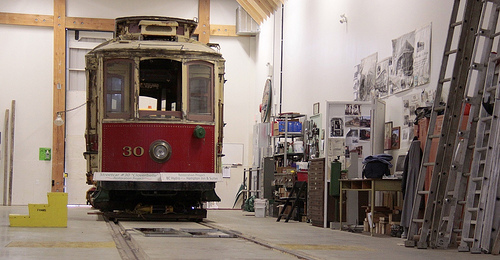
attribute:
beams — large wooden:
[51, 2, 67, 192]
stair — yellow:
[45, 187, 70, 209]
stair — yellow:
[27, 200, 50, 217]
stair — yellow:
[9, 210, 31, 227]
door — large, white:
[79, 69, 117, 186]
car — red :
[71, 7, 231, 218]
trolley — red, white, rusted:
[79, 15, 221, 225]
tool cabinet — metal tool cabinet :
[306, 157, 324, 225]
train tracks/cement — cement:
[109, 217, 286, 258]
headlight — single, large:
[150, 140, 172, 164]